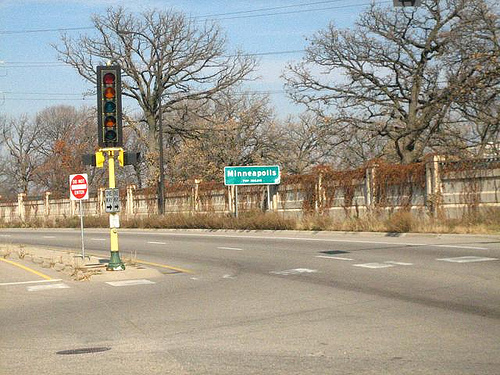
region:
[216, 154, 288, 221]
green sign on right side of road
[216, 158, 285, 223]
green sign holding by two poles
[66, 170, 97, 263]
a sign on the street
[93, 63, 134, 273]
a traffic light on corner of street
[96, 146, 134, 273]
pole of traffic light is yellow and green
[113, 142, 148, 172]
peatonal sign on right side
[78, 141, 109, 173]
peatonal sign on left side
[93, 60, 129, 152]
the traffic light is off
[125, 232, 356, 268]
white dotted lines on road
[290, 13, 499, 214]
a tree behind a wall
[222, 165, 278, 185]
long, rectangular green city limits sign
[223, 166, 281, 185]
city limits sign at entrance to Minneapolis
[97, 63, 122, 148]
all lights on traffic signal are dark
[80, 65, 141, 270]
traffic signal mounted on yellow, metal pole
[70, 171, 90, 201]
red and white square sign warns do not enter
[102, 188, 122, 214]
bac-to-back one way signs on traffic signal pole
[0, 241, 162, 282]
concrete median between two one-way roads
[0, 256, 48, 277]
yellow stripe to left of concrete median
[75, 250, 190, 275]
yellow stripe to right of concrete median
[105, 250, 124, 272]
base of traffic signal pole is painted green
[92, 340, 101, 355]
part of a shadow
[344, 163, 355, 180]
edge of a wall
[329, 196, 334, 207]
part of a fence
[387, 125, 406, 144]
edge of a tree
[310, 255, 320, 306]
part of the road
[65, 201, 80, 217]
part of the road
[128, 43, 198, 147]
the tree is bare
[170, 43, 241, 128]
the tree is bare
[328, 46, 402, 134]
the tree is bare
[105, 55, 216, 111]
the tree is bare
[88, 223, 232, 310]
the street is paved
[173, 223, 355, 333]
the street is paved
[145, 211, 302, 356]
the street is paved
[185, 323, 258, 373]
the street is paved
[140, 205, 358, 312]
the street is empty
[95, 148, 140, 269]
the pole is yellow